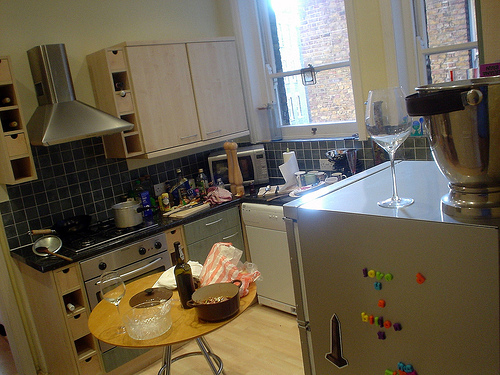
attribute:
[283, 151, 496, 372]
fridge — white 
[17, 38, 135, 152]
vent — silver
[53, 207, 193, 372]
stove — stainless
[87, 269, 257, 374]
table — brown 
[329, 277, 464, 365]
magnets — letter shaped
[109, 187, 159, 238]
cooker — pressurized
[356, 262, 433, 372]
letters — different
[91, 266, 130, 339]
glass — wine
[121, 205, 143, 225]
pot — metal, large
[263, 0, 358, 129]
window — beautiful 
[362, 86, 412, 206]
glass — for wine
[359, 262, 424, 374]
letters — different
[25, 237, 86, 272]
spoon — wooden 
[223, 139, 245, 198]
mills — wooden, salt, pepper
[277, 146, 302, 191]
paper towel — rolled, white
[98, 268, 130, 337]
glass — empty, for wine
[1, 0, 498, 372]
kitchen — beautiful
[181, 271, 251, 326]
lid — for pot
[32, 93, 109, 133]
chimney — vent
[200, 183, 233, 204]
rag — pink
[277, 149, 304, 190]
towels — white 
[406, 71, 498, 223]
ice bucket — metal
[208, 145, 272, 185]
microwave — silver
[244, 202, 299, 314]
dishwasher — white 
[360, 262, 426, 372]
stickies — colored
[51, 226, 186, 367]
oven — silver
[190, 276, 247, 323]
pot — brown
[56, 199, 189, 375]
stove — silver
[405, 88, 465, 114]
handle — black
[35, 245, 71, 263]
spoon — wooden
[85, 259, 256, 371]
table — brown